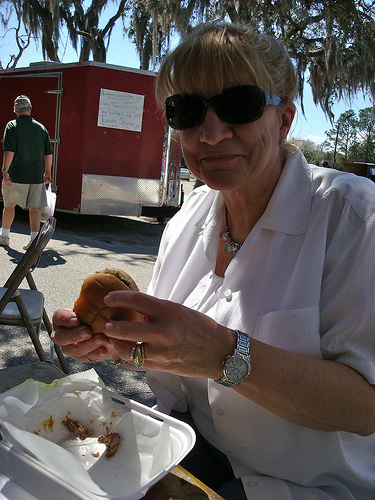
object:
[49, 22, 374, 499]
lady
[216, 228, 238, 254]
trinket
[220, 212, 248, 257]
necklace